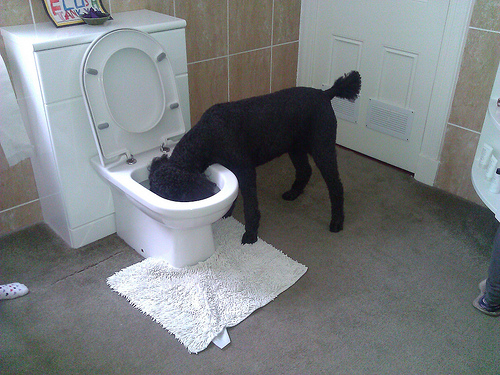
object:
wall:
[0, 0, 307, 246]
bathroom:
[1, 2, 498, 372]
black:
[146, 72, 361, 243]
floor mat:
[105, 213, 307, 354]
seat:
[82, 28, 186, 164]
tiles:
[187, 5, 294, 89]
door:
[297, 1, 473, 186]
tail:
[325, 70, 362, 103]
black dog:
[148, 71, 361, 244]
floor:
[0, 144, 499, 374]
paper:
[0, 58, 35, 167]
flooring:
[375, 185, 450, 240]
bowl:
[98, 147, 238, 230]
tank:
[0, 8, 192, 249]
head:
[146, 156, 212, 203]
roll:
[0, 58, 14, 84]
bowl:
[79, 11, 110, 25]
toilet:
[79, 27, 239, 266]